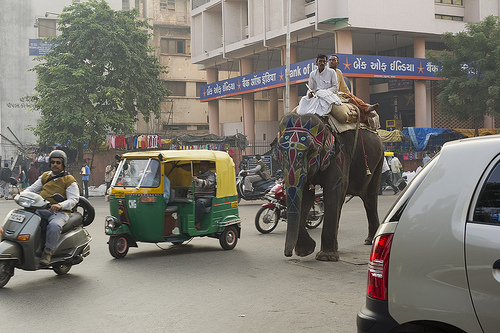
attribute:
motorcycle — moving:
[0, 192, 105, 284]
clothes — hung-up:
[88, 125, 193, 150]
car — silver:
[355, 129, 499, 331]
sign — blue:
[199, 54, 478, 102]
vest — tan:
[38, 173, 74, 200]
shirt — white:
[18, 171, 80, 208]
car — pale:
[329, 89, 497, 331]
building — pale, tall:
[238, 21, 495, 156]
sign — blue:
[188, 44, 455, 99]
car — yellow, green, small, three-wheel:
[100, 143, 241, 260]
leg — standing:
[360, 180, 381, 242]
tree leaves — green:
[18, 0, 171, 152]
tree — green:
[21, 0, 176, 182]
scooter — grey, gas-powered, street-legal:
[0, 186, 105, 279]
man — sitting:
[15, 140, 87, 271]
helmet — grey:
[46, 148, 70, 170]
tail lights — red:
[367, 231, 399, 316]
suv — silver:
[301, 84, 498, 314]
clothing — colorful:
[103, 132, 246, 166]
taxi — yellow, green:
[92, 131, 263, 275]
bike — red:
[250, 175, 330, 236]